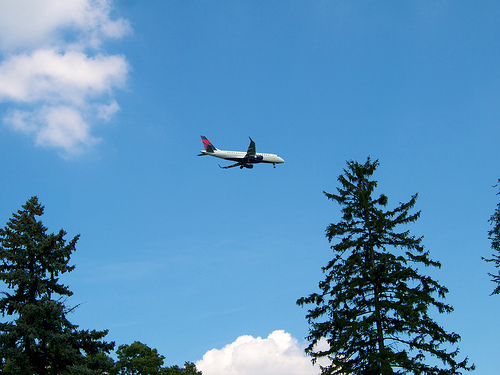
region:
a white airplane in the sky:
[173, 124, 308, 199]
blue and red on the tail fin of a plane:
[198, 130, 213, 154]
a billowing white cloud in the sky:
[196, 306, 288, 374]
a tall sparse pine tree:
[308, 143, 451, 373]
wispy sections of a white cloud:
[10, 41, 107, 154]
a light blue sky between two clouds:
[124, 179, 267, 307]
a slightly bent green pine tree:
[1, 179, 138, 374]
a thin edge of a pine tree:
[484, 164, 498, 270]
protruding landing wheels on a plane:
[263, 158, 281, 177]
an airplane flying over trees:
[36, 32, 498, 349]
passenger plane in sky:
[189, 134, 287, 171]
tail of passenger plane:
[193, 131, 218, 158]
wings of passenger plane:
[218, 133, 257, 177]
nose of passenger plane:
[265, 149, 283, 169]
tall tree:
[297, 157, 472, 374]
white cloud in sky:
[0, 3, 128, 165]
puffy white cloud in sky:
[179, 326, 321, 373]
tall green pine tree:
[2, 195, 84, 374]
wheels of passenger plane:
[268, 162, 279, 169]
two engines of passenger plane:
[243, 153, 261, 168]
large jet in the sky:
[188, 127, 288, 176]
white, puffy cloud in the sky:
[197, 325, 297, 372]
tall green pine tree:
[293, 148, 473, 373]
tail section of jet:
[192, 130, 219, 160]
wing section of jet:
[215, 138, 259, 171]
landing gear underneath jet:
[268, 161, 279, 171]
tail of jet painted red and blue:
[196, 131, 216, 161]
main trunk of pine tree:
[359, 185, 393, 371]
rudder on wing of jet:
[241, 122, 259, 154]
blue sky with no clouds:
[287, 16, 484, 114]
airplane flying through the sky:
[168, 99, 307, 185]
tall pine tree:
[299, 151, 454, 373]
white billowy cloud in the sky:
[177, 294, 331, 373]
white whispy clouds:
[2, 8, 164, 173]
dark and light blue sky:
[16, 21, 481, 356]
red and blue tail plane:
[183, 119, 225, 170]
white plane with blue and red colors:
[171, 116, 323, 206]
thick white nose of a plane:
[264, 144, 294, 181]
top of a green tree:
[89, 309, 196, 373]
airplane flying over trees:
[2, 34, 481, 370]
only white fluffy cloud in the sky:
[191, 328, 332, 373]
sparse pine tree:
[295, 155, 475, 371]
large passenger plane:
[195, 134, 285, 170]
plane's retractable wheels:
[270, 160, 277, 170]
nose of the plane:
[277, 150, 287, 166]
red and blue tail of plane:
[196, 130, 211, 150]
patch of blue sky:
[120, 215, 247, 325]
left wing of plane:
[215, 160, 240, 170]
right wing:
[245, 132, 259, 157]